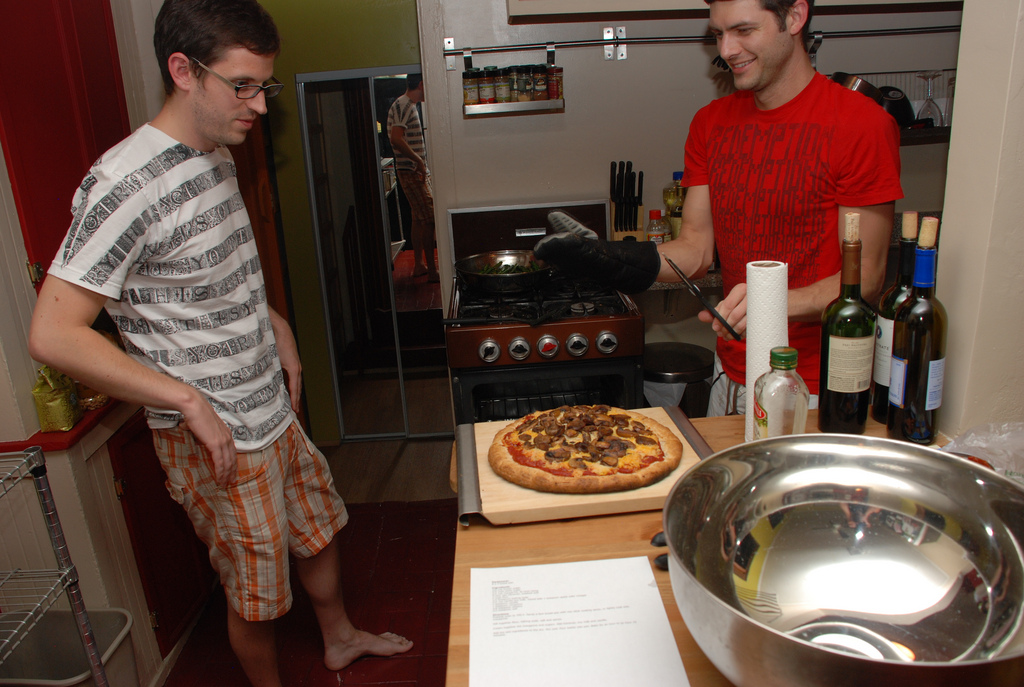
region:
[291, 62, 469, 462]
There is a mirrored door behind the man.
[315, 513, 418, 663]
the kitchen floor has tiles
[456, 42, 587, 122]
Aluminum spice shelf with six spices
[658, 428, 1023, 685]
Two aluminum mixing bowls sitting on a table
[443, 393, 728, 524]
Pepperoni, Cheese, and meat pizza with a thick crust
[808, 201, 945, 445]
Three bottle of cooking wine sitting on table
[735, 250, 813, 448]
Olive oil and paper towels sitting on table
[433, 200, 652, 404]
Brown gas stove with black and red dials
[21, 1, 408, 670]
Man wearing glasses standing in kitchen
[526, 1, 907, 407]
Man smiling wearing a black oven mitt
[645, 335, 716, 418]
Silver trash can sitting in kitchen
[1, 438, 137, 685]
Aluminum tierd shelf and gray trash can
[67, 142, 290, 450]
the shirt is stripes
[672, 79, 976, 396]
the t-shirt is red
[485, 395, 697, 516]
pizza on the table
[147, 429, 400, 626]
the short is orange and beige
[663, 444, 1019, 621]
stainless bowl on table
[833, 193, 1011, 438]
three wine bottles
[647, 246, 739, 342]
the man is holding scissors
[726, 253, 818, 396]
tissue on the table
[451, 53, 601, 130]
condiments are hanging by the stove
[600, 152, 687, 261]
knives are beside the stove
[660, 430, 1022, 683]
large metal mixing bowl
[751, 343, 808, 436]
olive oil bottle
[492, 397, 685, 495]
pizza topped with cheese and meat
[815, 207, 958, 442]
three open wine bottles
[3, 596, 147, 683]
plastic trash receptacle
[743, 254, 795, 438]
roll of white paper towels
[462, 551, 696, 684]
paper with a printed recipe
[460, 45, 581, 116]
hanging metal spice rack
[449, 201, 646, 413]
a rather small stove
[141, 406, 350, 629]
orange and white shorts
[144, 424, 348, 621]
orange plaid shorts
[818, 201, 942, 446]
three wine bottles with corks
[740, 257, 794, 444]
roll of paper towels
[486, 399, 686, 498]
cooked pizza on breadboard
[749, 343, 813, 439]
bottle of olive oil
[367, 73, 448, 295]
reflection of man in mirror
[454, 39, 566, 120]
hanging rack of spices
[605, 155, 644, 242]
set of carving knives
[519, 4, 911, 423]
man wearing an oven mitt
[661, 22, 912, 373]
Guy wearing a red shirt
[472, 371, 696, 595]
A whole pizza pie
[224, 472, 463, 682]
A guy is barefoot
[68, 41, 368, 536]
A guy is wearing a black and white striped shirt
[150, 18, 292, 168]
Guy has on eyeglasses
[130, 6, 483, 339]
Man's reflection in the mirror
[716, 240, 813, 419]
A roll of white paper towels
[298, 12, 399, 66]
The wall is yellow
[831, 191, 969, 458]
Three bottles of wine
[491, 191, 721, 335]
A black oven mitt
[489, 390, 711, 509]
home cooked pizza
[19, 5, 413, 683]
barefoot man with orange plaid shorts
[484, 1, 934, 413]
man with a red shirt and oven mitt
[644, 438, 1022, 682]
large silver baking cooking bowls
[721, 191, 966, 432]
wine bottles and paper towels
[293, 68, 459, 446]
mirror with man's reflection in it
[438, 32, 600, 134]
small hanging spice rack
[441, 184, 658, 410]
oven and stove in kitchen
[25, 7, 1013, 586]
two men cooking